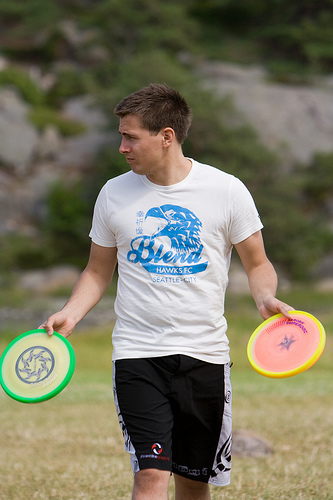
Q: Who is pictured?
A: A man.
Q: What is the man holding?
A: Frisbees.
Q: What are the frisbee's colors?
A: Pink, yellow and green.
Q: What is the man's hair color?
A: Brown.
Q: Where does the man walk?
A: On grass.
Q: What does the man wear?
A: Black shorts.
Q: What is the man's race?
A: Caucasian.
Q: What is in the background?
A: A hill dotted with foliage.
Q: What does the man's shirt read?
A: Blend.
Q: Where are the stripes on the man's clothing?
A: Shorts.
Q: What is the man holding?
A: Frisbees.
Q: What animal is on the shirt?
A: A hawk.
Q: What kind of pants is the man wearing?
A: Shorts,.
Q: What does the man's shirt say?
A: Blend Hawks FC.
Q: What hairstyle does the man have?
A: Short hair.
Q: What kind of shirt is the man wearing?
A: A tee shirt.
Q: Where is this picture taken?
A: A park.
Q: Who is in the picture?
A: A man.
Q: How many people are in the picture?
A: One.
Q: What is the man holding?
A: Frisbees.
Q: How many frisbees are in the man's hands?
A: Two.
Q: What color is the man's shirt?
A: White.